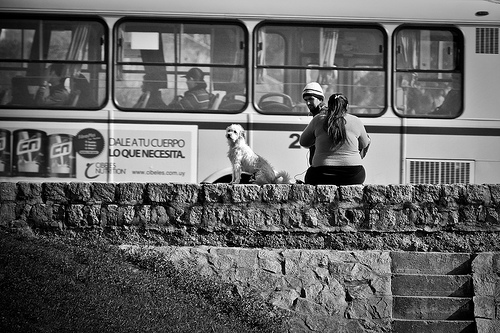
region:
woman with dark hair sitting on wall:
[300, 88, 377, 183]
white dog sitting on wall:
[219, 117, 296, 189]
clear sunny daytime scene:
[4, 0, 491, 329]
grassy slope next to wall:
[3, 229, 410, 325]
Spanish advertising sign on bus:
[5, 120, 193, 176]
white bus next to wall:
[3, 2, 498, 176]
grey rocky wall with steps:
[4, 185, 496, 315]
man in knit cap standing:
[300, 74, 334, 182]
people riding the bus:
[13, 19, 465, 108]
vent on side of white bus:
[400, 159, 484, 187]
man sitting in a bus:
[169, 67, 229, 110]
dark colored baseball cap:
[176, 64, 207, 86]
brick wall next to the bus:
[13, 188, 497, 267]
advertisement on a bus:
[5, 127, 202, 185]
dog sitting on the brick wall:
[219, 114, 302, 196]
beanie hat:
[299, 74, 329, 99]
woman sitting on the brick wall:
[300, 88, 399, 188]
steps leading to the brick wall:
[385, 242, 485, 328]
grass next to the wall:
[7, 240, 215, 331]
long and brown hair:
[324, 93, 354, 158]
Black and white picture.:
[55, 65, 425, 265]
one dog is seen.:
[217, 122, 268, 197]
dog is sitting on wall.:
[206, 123, 282, 203]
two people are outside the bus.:
[282, 80, 352, 191]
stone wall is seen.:
[36, 195, 336, 310]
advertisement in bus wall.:
[1, 112, 198, 182]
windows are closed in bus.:
[17, 26, 474, 132]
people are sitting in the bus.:
[22, 52, 229, 127]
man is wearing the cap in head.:
[296, 81, 326, 116]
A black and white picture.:
[17, 10, 443, 305]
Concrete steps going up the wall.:
[383, 243, 479, 329]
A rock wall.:
[27, 180, 452, 242]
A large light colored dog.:
[215, 115, 287, 191]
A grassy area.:
[12, 225, 223, 328]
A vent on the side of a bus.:
[397, 142, 488, 182]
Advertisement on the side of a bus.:
[0, 72, 216, 179]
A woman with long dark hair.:
[305, 90, 380, 181]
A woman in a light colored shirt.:
[292, 91, 375, 177]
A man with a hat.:
[284, 72, 326, 119]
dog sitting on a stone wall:
[220, 120, 296, 187]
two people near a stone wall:
[296, 80, 373, 191]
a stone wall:
[1, 179, 498, 331]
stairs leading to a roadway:
[384, 245, 484, 330]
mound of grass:
[3, 224, 272, 331]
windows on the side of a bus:
[1, 7, 471, 124]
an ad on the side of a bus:
[1, 119, 205, 185]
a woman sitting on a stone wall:
[292, 92, 371, 187]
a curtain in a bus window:
[313, 24, 340, 103]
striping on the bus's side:
[0, 113, 499, 142]